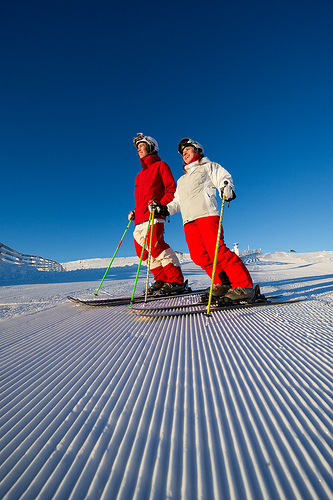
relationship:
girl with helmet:
[168, 132, 210, 214] [118, 126, 212, 173]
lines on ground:
[72, 266, 99, 452] [113, 332, 254, 456]